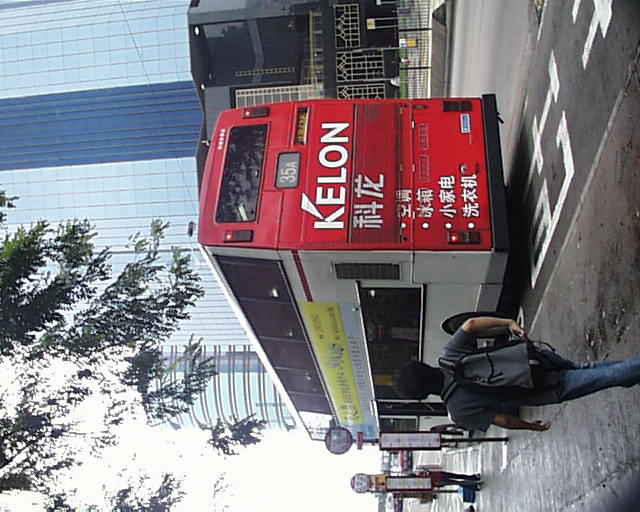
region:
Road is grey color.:
[462, 22, 618, 160]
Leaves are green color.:
[4, 242, 138, 451]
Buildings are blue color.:
[7, 103, 236, 410]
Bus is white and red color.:
[185, 167, 515, 441]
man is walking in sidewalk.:
[376, 307, 639, 426]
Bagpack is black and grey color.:
[439, 347, 570, 401]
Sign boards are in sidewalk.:
[323, 420, 558, 498]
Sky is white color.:
[70, 420, 326, 506]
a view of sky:
[260, 456, 312, 497]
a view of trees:
[65, 305, 150, 390]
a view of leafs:
[176, 401, 284, 458]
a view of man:
[435, 366, 546, 444]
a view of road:
[561, 419, 602, 468]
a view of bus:
[185, 283, 569, 477]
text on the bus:
[275, 110, 362, 220]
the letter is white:
[298, 192, 343, 226]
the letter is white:
[319, 165, 347, 185]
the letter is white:
[321, 123, 345, 144]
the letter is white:
[354, 174, 384, 196]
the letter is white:
[351, 203, 384, 224]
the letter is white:
[397, 188, 411, 201]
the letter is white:
[396, 202, 412, 215]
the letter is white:
[411, 187, 425, 205]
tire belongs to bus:
[444, 310, 508, 336]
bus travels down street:
[197, 90, 514, 451]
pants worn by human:
[527, 344, 639, 409]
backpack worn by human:
[438, 338, 541, 414]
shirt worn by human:
[443, 326, 530, 433]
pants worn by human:
[443, 468, 477, 489]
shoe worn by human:
[472, 471, 481, 480]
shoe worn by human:
[476, 481, 484, 492]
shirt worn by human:
[425, 467, 443, 484]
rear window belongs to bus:
[216, 118, 267, 224]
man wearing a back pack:
[439, 343, 540, 395]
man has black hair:
[387, 361, 446, 401]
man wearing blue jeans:
[525, 335, 637, 399]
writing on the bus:
[297, 120, 501, 256]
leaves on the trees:
[4, 222, 238, 506]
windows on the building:
[26, 148, 186, 215]